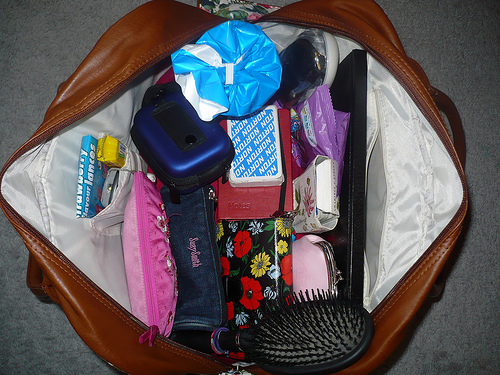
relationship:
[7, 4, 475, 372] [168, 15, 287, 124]
bag filled with item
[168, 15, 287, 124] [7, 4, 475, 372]
item in bag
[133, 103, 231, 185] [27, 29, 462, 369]
case in bag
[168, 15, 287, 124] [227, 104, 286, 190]
item in stack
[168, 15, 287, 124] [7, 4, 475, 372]
item inside bag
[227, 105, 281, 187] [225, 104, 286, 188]
stack of cards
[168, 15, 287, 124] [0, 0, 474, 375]
item in bag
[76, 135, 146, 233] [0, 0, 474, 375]
interior pocket in bag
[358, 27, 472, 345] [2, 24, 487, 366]
zipper on brown bag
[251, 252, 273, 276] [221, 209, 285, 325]
flower on background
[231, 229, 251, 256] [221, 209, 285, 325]
flower on background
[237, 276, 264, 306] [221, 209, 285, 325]
flower on background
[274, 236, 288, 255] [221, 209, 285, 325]
flower on background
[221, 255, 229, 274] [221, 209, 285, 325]
flower on background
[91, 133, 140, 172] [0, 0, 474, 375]
candy in bag